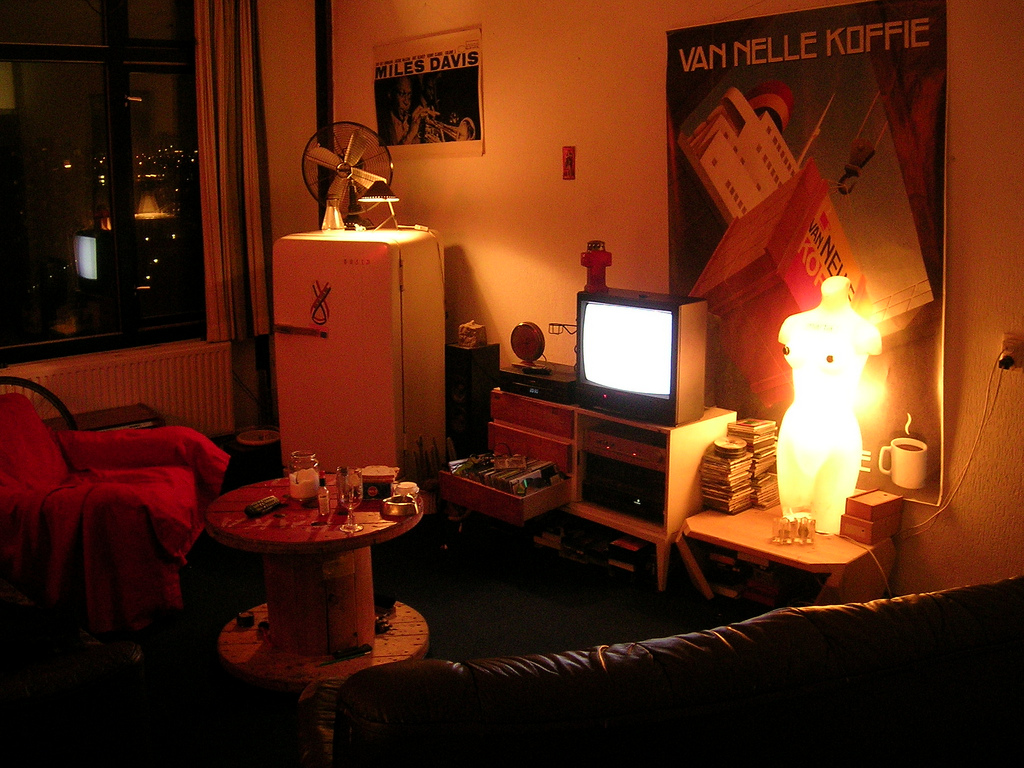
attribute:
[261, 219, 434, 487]
refrigerator — white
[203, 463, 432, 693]
table — round, wood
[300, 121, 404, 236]
fan — electrical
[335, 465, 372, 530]
wine glass — clear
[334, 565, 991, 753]
couch — brown, leather